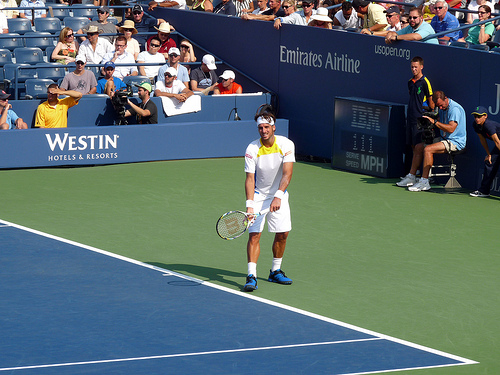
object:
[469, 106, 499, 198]
boy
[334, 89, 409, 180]
tracker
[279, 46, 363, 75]
sponsers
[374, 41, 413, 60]
sponsers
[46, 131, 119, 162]
sponsers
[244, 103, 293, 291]
calves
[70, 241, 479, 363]
lines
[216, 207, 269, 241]
racket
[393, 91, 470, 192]
man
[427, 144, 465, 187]
chair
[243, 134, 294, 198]
white shirt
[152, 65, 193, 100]
man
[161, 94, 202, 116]
towel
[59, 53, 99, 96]
person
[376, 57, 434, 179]
person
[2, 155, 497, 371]
tennis court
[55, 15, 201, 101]
hot sauce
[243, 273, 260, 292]
shoe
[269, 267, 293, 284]
shoe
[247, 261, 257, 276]
sock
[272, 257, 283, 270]
sock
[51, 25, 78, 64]
person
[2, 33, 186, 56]
stands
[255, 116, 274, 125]
headband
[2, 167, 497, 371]
court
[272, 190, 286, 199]
wristband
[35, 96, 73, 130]
yellow shirt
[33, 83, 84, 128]
man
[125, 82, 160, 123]
person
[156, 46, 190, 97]
person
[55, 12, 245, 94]
spectators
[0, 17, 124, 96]
seats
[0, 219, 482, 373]
baseline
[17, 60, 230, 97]
stands